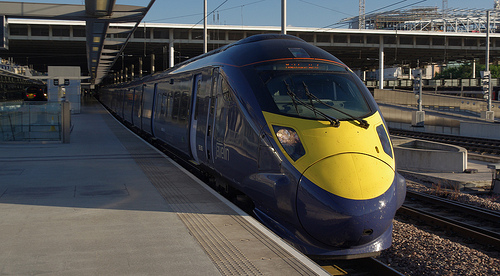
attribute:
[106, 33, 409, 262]
train — empty, long, round, blue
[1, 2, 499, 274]
station — built, metal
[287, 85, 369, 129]
wipers — black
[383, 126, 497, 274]
tracks — brown, metal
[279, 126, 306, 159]
headlight — small, round, lit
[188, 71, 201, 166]
door — blue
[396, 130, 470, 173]
pillar — cement, gray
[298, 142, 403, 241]
nose — yellow, blue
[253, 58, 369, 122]
windsheild — large, black, glass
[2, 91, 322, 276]
walkway — large, gray, grey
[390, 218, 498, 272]
gravel — gray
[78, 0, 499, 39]
sky — blue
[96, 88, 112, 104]
lights — red